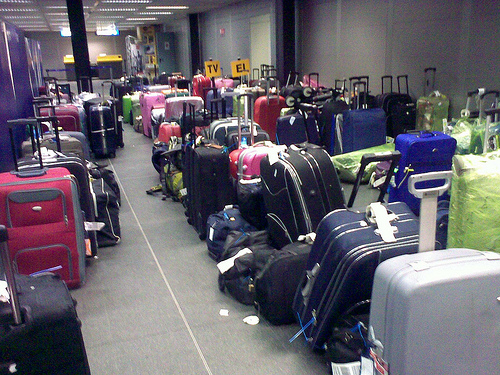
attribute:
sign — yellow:
[228, 59, 252, 76]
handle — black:
[245, 147, 317, 179]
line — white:
[103, 151, 218, 373]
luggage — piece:
[0, 119, 84, 275]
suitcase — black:
[259, 139, 345, 249]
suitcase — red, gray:
[0, 117, 87, 289]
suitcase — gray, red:
[250, 73, 284, 140]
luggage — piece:
[296, 203, 419, 339]